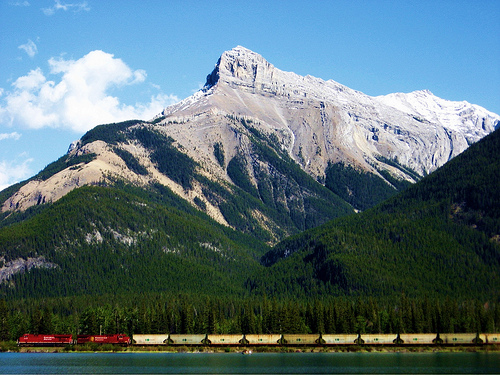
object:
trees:
[454, 301, 499, 334]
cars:
[205, 334, 244, 345]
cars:
[168, 333, 210, 346]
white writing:
[44, 336, 56, 340]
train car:
[16, 331, 74, 348]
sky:
[0, 0, 499, 190]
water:
[0, 351, 167, 373]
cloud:
[1, 48, 180, 133]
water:
[186, 352, 347, 373]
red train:
[17, 333, 74, 347]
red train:
[76, 334, 131, 347]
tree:
[246, 308, 264, 335]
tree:
[221, 304, 241, 331]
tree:
[311, 297, 328, 336]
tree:
[324, 300, 337, 331]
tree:
[335, 314, 354, 333]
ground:
[338, 271, 479, 331]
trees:
[6, 302, 57, 336]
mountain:
[0, 45, 499, 330]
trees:
[111, 289, 184, 333]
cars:
[131, 333, 170, 347]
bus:
[16, 333, 500, 348]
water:
[465, 344, 500, 375]